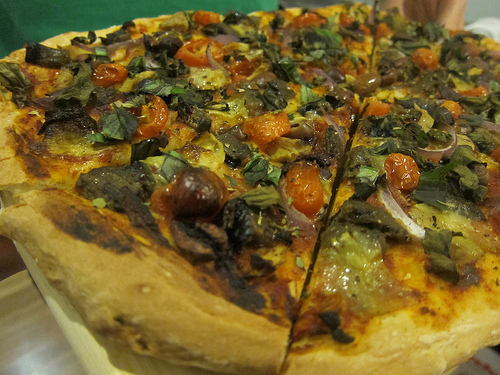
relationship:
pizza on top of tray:
[12, 9, 499, 366] [10, 229, 168, 374]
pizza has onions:
[12, 9, 499, 366] [375, 186, 427, 238]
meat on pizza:
[22, 40, 71, 67] [12, 9, 499, 366]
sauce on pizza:
[186, 67, 232, 94] [12, 9, 499, 366]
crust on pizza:
[12, 161, 333, 374] [12, 9, 499, 366]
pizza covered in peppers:
[12, 9, 499, 366] [278, 55, 312, 90]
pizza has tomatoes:
[12, 9, 499, 366] [181, 36, 230, 67]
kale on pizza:
[140, 78, 180, 93] [12, 9, 499, 366]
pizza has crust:
[12, 9, 499, 366] [12, 161, 333, 374]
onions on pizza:
[375, 186, 427, 238] [12, 9, 499, 366]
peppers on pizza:
[281, 55, 302, 81] [12, 9, 499, 366]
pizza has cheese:
[12, 9, 499, 366] [374, 227, 459, 305]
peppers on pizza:
[278, 55, 312, 90] [12, 9, 499, 366]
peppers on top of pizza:
[278, 55, 312, 90] [12, 9, 499, 366]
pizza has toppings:
[12, 9, 499, 366] [272, 29, 330, 60]